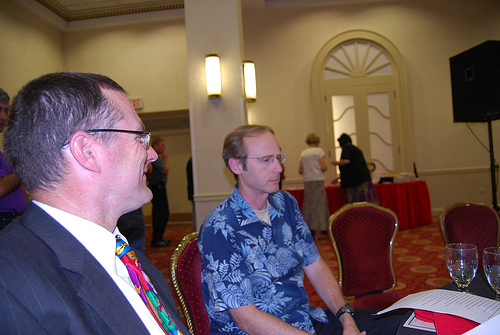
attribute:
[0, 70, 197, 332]
man — black, smiling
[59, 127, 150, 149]
glasses — black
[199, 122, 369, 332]
man — blond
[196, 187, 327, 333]
shirt — blue, floral, flowered, light blue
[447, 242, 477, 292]
glass — Empty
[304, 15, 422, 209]
doorway — Large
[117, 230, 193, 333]
tie — colorful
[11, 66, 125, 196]
hair — gray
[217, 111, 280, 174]
hair — brown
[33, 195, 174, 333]
shirt — white, collared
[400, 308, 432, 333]
paper — Printed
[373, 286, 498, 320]
paper — Printed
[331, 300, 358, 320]
watch — black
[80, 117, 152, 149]
glasses — black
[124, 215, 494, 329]
carpet — red, yellow, ornate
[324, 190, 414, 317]
chair — red , ornate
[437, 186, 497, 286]
chair — red , ornate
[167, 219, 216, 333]
chair — red , ornate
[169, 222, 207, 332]
frame — gold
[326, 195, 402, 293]
frame — gold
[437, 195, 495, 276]
frame — gold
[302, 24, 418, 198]
doorway — white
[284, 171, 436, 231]
tablecloth — red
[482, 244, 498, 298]
glasses — empty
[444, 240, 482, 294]
glasses — empty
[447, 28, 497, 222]
speaker — black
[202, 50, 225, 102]
light — illuminated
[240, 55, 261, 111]
light — illuminated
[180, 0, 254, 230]
pillar — white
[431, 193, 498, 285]
chair — red, gold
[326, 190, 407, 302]
chair — red, gold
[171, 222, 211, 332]
chair — red, gold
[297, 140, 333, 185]
shirt — white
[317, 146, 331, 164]
sleeve — white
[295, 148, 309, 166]
sleeve — white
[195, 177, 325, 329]
shirt — blue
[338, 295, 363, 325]
wristwatch — black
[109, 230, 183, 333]
tie — colorful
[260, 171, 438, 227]
tablecloth — red, long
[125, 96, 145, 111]
exit sign — red, white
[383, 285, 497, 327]
sheet — white, paper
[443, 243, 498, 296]
glasses — empty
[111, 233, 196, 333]
tie — multi-colored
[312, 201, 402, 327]
chair — empty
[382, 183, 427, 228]
table cloth — red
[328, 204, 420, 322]
chair — red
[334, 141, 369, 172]
shirt — black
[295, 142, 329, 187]
shirt — white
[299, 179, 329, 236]
skirt — tanned